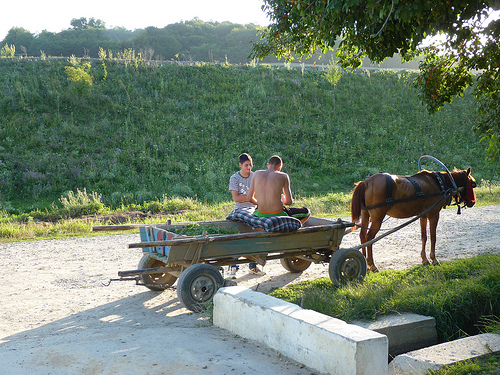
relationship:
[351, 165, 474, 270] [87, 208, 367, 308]
brown horse pulling cart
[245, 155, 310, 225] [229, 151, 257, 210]
man talking to men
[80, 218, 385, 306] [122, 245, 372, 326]
wood wagon on wheels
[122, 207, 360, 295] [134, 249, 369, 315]
cart with wheels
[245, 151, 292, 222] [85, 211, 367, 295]
man sitting on cart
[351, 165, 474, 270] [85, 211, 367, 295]
brown horse to a cart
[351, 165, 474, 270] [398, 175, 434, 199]
brown horse with ribs